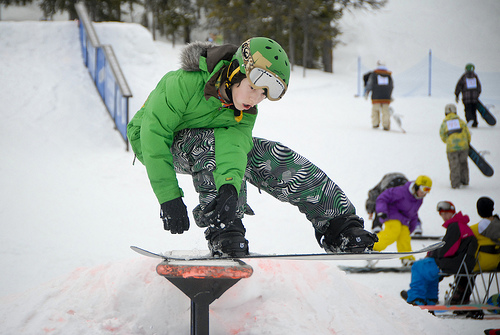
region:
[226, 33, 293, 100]
a green helmet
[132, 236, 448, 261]
a gray snowboard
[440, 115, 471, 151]
a yellow jacket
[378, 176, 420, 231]
a purple jacket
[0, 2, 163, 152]
a hill of snow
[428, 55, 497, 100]
a portion of a fence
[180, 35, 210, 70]
a small piece of gray coat fur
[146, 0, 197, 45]
part of a green tree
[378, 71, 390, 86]
a player's bib number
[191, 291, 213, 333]
a short black pole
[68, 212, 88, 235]
Small patch of snow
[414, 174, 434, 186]
Yellow helmet of snowboarder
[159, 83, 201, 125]
Green jacket of snowboarder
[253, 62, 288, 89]
White and brown goggles of snowboarder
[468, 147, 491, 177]
Blue and black snowboard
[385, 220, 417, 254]
Yellow sweatpants of snowboarder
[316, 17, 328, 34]
Leaves on the tree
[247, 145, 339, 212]
Decorated sweatpants of snowboarder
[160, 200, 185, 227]
Right black glove of snowboarder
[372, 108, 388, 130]
Khaki sweatpants of snowboarder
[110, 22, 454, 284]
A boy in a green jacket on a snowboard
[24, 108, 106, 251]
White snow on the slope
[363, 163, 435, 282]
A snowboarder wearing a purple jacket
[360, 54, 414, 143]
A snowboarder walking up the slope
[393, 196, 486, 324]
A boy wearing goggles on his head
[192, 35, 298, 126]
A boy wearing a green helmet with goggles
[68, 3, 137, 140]
A blue fence in the background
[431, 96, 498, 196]
A person with camoflauge pants carrying a snowboard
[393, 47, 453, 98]
A blue wire fence in the background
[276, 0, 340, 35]
Green trees in the background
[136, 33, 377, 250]
snowboarding kid wearing green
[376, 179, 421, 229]
purple winter coat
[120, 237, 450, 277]
this is a snowboard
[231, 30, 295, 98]
kid wearing green helmet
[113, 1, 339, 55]
a bunch of trees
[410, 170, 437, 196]
yellow safety helmet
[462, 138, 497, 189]
this is a snowboard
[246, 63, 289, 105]
these are safety googles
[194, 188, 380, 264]
snow boots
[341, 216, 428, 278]
snowboarder wearing yellow pants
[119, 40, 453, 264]
a boy snowboarding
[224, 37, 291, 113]
boy with a green helmet and goggles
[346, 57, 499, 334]
kids on a snowy hill with snowboards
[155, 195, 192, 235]
gloved hand of a boy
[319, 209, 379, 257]
left foot of a snowboarder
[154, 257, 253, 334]
a black and orange metal rail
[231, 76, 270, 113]
the face of a bou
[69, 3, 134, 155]
two rails for grinding with a snowboard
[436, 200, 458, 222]
head of a young man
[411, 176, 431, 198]
head of a young person